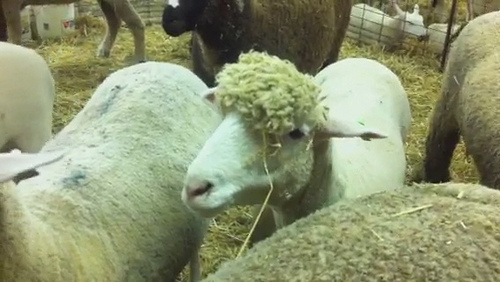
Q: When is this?
A: Daytime.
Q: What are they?
A: Sheep.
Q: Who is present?
A: Nobody.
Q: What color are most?
A: White.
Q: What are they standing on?
A: Hay.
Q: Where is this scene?
A: At a farm.